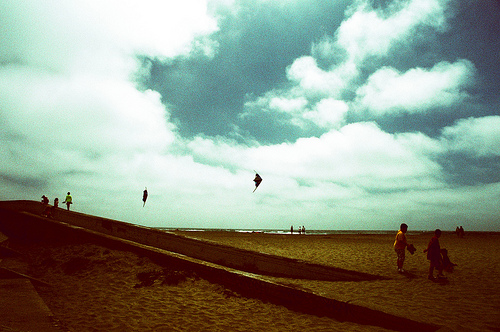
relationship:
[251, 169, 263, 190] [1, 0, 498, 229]
kite in sky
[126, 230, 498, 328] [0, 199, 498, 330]
beach has sand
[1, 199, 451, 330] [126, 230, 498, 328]
hill on beach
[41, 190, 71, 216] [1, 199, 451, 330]
people are on hill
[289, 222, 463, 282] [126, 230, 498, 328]
people are on beach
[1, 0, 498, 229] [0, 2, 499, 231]
sky has clouds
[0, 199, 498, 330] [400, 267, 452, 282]
sand has shadow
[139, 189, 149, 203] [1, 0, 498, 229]
kite in sky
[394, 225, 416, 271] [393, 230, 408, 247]
person wearing yellow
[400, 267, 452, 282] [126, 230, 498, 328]
shadow on beach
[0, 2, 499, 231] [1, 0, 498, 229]
clouds in sky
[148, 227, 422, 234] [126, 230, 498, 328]
water near beach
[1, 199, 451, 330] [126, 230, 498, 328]
hill leading to beach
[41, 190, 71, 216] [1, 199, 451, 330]
people walking up hill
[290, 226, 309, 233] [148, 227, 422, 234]
people standing near water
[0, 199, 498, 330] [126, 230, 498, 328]
sand at beach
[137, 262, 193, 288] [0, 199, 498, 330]
weeds in sand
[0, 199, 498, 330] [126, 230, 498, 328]
sand on beach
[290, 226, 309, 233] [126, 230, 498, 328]
people are on beach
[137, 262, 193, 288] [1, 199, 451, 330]
weeds are on hill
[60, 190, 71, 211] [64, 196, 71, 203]
person wearing green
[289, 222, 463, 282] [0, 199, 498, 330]
people playing in sand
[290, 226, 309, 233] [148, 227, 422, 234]
people at water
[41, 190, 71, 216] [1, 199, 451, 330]
people on hill